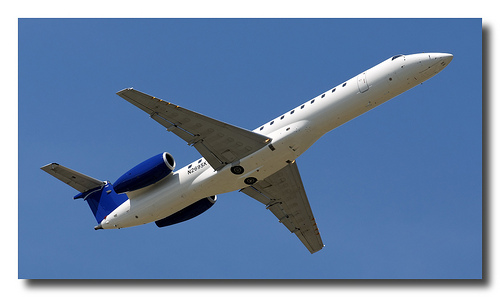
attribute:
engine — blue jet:
[112, 151, 177, 194]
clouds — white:
[27, 43, 117, 141]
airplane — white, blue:
[72, 25, 462, 250]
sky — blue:
[231, 45, 278, 72]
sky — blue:
[19, 17, 480, 279]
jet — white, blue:
[36, 49, 456, 256]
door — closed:
[352, 73, 375, 97]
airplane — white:
[36, 41, 453, 254]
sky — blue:
[330, 127, 482, 279]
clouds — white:
[44, 78, 121, 138]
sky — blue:
[64, 32, 318, 86]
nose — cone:
[400, 45, 459, 82]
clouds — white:
[344, 132, 460, 249]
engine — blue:
[105, 143, 181, 197]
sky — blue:
[360, 130, 442, 275]